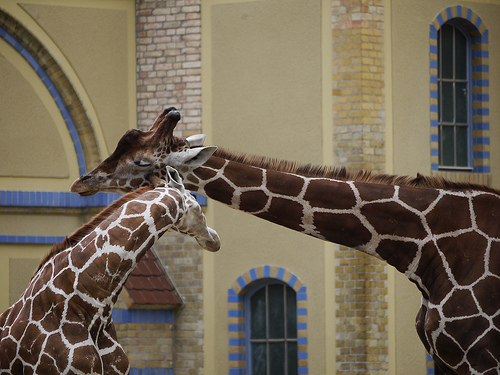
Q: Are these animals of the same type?
A: Yes, all the animals are giraffes.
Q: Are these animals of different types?
A: No, all the animals are giraffes.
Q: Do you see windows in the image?
A: Yes, there is a window.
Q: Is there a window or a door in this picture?
A: Yes, there is a window.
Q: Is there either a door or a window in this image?
A: Yes, there is a window.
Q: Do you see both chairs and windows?
A: No, there is a window but no chairs.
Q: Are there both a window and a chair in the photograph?
A: No, there is a window but no chairs.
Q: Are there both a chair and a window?
A: No, there is a window but no chairs.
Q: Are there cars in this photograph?
A: No, there are no cars.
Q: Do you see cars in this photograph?
A: No, there are no cars.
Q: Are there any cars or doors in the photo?
A: No, there are no cars or doors.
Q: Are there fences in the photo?
A: No, there are no fences.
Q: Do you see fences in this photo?
A: No, there are no fences.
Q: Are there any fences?
A: No, there are no fences.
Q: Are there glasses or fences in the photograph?
A: No, there are no fences or glasses.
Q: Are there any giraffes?
A: Yes, there is a giraffe.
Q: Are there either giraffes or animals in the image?
A: Yes, there is a giraffe.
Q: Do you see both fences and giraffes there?
A: No, there is a giraffe but no fences.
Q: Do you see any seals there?
A: No, there are no seals.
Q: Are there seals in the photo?
A: No, there are no seals.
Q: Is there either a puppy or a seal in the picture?
A: No, there are no seals or puppies.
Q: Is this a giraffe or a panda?
A: This is a giraffe.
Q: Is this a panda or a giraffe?
A: This is a giraffe.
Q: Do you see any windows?
A: Yes, there is a window.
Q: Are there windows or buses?
A: Yes, there is a window.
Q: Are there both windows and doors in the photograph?
A: No, there is a window but no doors.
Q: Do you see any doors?
A: No, there are no doors.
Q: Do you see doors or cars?
A: No, there are no doors or cars.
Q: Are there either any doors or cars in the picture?
A: No, there are no doors or cars.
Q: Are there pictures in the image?
A: No, there are no pictures.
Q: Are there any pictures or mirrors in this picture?
A: No, there are no pictures or mirrors.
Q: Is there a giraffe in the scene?
A: Yes, there is a giraffe.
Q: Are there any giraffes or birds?
A: Yes, there is a giraffe.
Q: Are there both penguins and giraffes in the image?
A: No, there is a giraffe but no penguins.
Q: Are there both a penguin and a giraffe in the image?
A: No, there is a giraffe but no penguins.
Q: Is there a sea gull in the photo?
A: No, there are no seagulls.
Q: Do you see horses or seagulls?
A: No, there are no seagulls or horses.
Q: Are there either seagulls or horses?
A: No, there are no seagulls or horses.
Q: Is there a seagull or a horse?
A: No, there are no seagulls or horses.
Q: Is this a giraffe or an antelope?
A: This is a giraffe.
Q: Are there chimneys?
A: No, there are no chimneys.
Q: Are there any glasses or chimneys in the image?
A: No, there are no chimneys or glasses.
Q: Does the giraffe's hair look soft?
A: Yes, the hair is soft.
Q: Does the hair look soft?
A: Yes, the hair is soft.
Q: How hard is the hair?
A: The hair is soft.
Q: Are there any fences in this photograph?
A: No, there are no fences.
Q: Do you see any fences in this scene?
A: No, there are no fences.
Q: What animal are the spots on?
A: The spots are on the giraffe.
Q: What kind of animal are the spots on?
A: The spots are on the giraffe.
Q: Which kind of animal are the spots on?
A: The spots are on the giraffe.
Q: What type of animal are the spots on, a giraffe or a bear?
A: The spots are on a giraffe.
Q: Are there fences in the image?
A: No, there are no fences.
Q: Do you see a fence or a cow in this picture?
A: No, there are no fences or cows.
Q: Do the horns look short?
A: Yes, the horns are short.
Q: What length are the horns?
A: The horns are short.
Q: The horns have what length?
A: The horns are short.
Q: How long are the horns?
A: The horns are short.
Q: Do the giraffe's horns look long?
A: No, the horns are short.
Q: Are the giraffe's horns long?
A: No, the horns are short.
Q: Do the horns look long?
A: No, the horns are short.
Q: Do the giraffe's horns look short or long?
A: The horns are short.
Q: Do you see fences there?
A: No, there are no fences.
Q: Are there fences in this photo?
A: No, there are no fences.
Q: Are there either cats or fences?
A: No, there are no fences or cats.